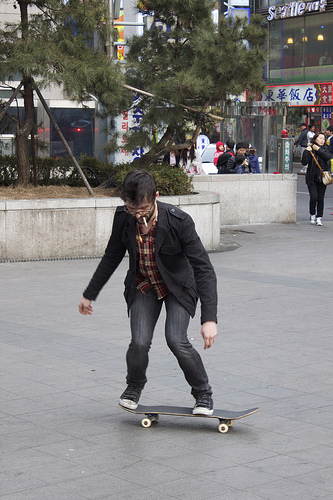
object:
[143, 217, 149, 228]
cigarette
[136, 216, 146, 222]
mouth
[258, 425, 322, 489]
ground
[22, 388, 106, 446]
cement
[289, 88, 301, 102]
word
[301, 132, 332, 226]
asian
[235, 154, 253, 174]
asian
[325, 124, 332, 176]
asian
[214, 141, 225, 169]
asian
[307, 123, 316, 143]
asian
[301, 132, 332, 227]
women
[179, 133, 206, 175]
women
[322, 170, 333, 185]
purse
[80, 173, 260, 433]
skateboarder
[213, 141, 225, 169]
coat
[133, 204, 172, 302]
shirt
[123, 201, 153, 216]
glasses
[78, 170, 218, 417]
man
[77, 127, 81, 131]
light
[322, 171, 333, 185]
bag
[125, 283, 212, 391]
jeans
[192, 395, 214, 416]
shoe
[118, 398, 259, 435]
skateboard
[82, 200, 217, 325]
coat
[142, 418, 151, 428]
wheel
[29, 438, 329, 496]
pavement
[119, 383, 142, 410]
shoe